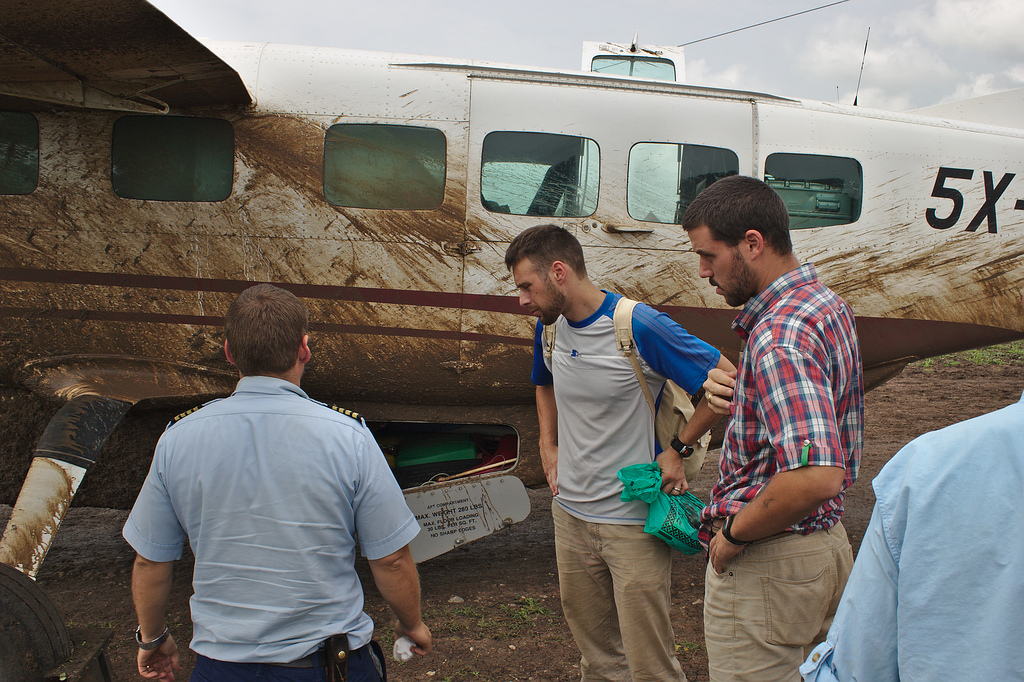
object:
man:
[117, 281, 443, 681]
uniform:
[109, 370, 423, 664]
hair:
[224, 281, 309, 378]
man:
[674, 171, 868, 681]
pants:
[699, 518, 869, 682]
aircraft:
[2, 0, 1024, 576]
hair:
[506, 225, 586, 279]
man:
[506, 223, 738, 679]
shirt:
[528, 287, 723, 525]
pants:
[551, 502, 688, 677]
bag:
[614, 461, 707, 556]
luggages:
[393, 434, 479, 469]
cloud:
[718, 7, 988, 91]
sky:
[153, 1, 1023, 109]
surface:
[6, 348, 991, 677]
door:
[402, 471, 533, 564]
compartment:
[370, 420, 528, 489]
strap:
[540, 325, 557, 364]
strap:
[613, 294, 659, 418]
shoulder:
[531, 318, 555, 342]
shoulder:
[605, 290, 676, 340]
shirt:
[698, 260, 863, 542]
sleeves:
[751, 344, 846, 473]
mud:
[16, 111, 496, 370]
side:
[0, 93, 992, 415]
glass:
[591, 55, 677, 83]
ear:
[550, 260, 567, 286]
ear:
[745, 229, 765, 261]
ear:
[300, 333, 313, 363]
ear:
[223, 336, 238, 368]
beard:
[532, 275, 565, 326]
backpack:
[540, 297, 714, 486]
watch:
[668, 436, 695, 459]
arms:
[638, 305, 742, 454]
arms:
[525, 323, 562, 449]